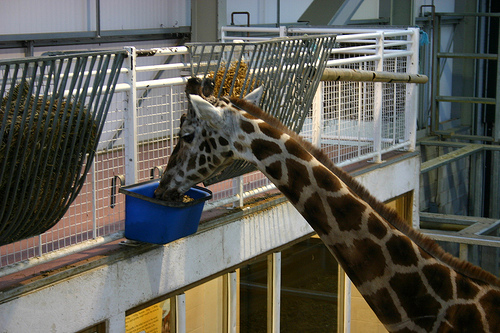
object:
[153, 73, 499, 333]
giraffe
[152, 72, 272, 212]
head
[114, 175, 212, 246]
container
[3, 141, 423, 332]
ledge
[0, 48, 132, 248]
container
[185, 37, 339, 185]
container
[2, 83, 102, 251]
hay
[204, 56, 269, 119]
hay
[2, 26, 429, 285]
fence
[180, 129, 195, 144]
eye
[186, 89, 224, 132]
ear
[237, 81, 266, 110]
ear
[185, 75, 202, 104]
horn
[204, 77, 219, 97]
horn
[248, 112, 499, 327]
neck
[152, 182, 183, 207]
mouth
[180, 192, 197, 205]
food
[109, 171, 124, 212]
hook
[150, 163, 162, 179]
hook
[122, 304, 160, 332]
sign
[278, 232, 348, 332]
window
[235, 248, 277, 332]
window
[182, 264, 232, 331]
window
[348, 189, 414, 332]
window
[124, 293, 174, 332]
window